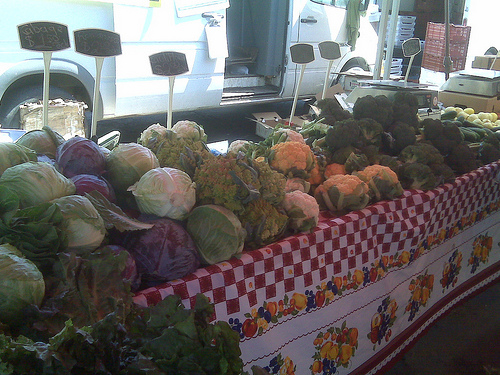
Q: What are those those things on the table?
A: Those things are vegetables.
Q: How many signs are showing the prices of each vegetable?
A: Six signs.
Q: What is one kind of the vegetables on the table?
A: Cabbage.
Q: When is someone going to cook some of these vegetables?
A: After buying the vegetable.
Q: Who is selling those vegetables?
A: The store owner.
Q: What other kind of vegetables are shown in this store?
A: Broccolis.